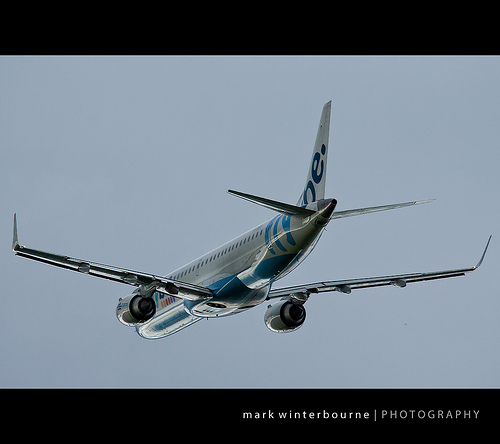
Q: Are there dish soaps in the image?
A: No, there are no dish soaps.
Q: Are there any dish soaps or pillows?
A: No, there are no dish soaps or pillows.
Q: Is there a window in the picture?
A: Yes, there are windows.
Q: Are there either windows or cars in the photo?
A: Yes, there are windows.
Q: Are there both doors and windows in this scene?
A: No, there are windows but no doors.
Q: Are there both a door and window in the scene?
A: No, there are windows but no doors.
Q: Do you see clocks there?
A: No, there are no clocks.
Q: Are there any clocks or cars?
A: No, there are no clocks or cars.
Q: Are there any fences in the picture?
A: No, there are no fences.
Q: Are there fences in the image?
A: No, there are no fences.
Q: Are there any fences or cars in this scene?
A: No, there are no fences or cars.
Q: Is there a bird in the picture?
A: No, there are no birds.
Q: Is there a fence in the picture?
A: No, there are no fences.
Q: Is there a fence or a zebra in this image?
A: No, there are no fences or zebras.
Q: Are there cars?
A: No, there are no cars.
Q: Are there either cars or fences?
A: No, there are no cars or fences.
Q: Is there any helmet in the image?
A: No, there are no helmets.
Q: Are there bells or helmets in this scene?
A: No, there are no helmets or bells.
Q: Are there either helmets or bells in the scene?
A: No, there are no helmets or bells.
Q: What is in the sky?
A: The clouds are in the sky.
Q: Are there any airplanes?
A: Yes, there is an airplane.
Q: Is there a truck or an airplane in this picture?
A: Yes, there is an airplane.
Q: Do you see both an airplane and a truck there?
A: No, there is an airplane but no trucks.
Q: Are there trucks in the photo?
A: No, there are no trucks.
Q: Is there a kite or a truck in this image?
A: No, there are no trucks or kites.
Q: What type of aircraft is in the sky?
A: The aircraft is an airplane.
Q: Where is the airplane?
A: The airplane is in the sky.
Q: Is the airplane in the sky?
A: Yes, the airplane is in the sky.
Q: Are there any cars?
A: No, there are no cars.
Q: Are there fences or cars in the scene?
A: No, there are no cars or fences.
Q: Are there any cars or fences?
A: No, there are no cars or fences.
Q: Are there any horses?
A: No, there are no horses.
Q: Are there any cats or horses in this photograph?
A: No, there are no horses or cats.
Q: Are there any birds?
A: No, there are no birds.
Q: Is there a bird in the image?
A: No, there are no birds.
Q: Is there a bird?
A: No, there are no birds.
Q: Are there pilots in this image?
A: No, there are no pilots.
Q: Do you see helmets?
A: No, there are no helmets.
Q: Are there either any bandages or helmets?
A: No, there are no helmets or bandages.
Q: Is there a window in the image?
A: Yes, there are windows.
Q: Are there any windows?
A: Yes, there are windows.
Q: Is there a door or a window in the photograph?
A: Yes, there are windows.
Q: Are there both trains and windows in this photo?
A: No, there are windows but no trains.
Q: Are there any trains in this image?
A: No, there are no trains.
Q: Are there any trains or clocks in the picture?
A: No, there are no trains or clocks.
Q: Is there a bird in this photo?
A: No, there are no birds.